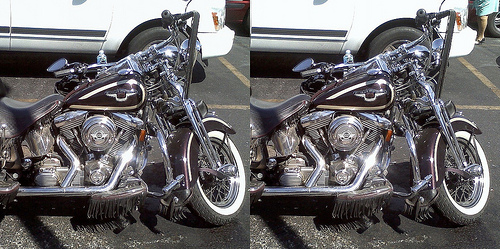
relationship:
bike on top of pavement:
[10, 17, 243, 236] [6, 32, 250, 248]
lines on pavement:
[205, 55, 251, 116] [6, 32, 250, 248]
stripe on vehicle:
[252, 25, 349, 46] [251, 0, 478, 81]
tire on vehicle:
[371, 30, 433, 74] [251, 0, 478, 81]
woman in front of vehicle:
[474, 1, 498, 47] [251, 0, 478, 81]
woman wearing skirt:
[474, 1, 498, 47] [475, 0, 497, 15]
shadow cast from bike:
[11, 202, 164, 244] [10, 17, 243, 236]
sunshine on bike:
[122, 147, 138, 164] [10, 17, 243, 236]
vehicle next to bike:
[251, 0, 478, 81] [10, 17, 243, 236]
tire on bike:
[189, 127, 246, 223] [10, 17, 243, 236]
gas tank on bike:
[62, 72, 149, 116] [10, 17, 243, 236]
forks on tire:
[202, 153, 232, 199] [189, 127, 246, 223]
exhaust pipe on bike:
[23, 156, 138, 208] [10, 17, 243, 236]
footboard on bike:
[98, 176, 147, 202] [10, 17, 243, 236]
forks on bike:
[202, 153, 232, 199] [10, 17, 243, 236]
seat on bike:
[1, 94, 62, 132] [10, 17, 243, 236]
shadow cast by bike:
[11, 202, 164, 244] [10, 17, 243, 236]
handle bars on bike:
[50, 14, 190, 74] [10, 17, 243, 236]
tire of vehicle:
[371, 30, 433, 74] [251, 0, 478, 81]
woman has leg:
[474, 1, 498, 47] [474, 17, 491, 41]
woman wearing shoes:
[474, 1, 498, 47] [476, 37, 488, 44]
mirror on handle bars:
[48, 53, 81, 73] [50, 14, 190, 74]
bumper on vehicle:
[450, 29, 479, 57] [251, 0, 478, 81]